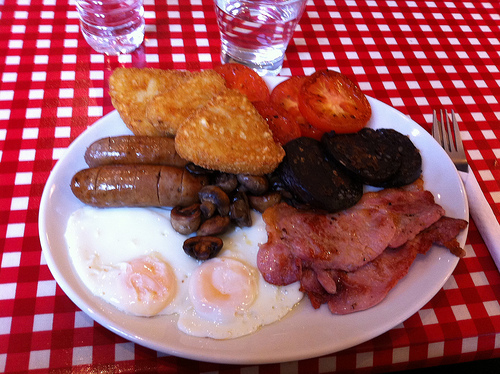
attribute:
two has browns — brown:
[108, 61, 287, 177]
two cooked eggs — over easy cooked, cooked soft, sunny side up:
[66, 198, 304, 342]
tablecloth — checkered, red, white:
[1, 1, 499, 373]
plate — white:
[38, 74, 470, 365]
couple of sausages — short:
[73, 134, 201, 208]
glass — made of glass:
[213, 2, 307, 78]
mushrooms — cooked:
[171, 159, 280, 260]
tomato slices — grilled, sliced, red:
[214, 59, 372, 142]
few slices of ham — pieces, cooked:
[259, 176, 468, 319]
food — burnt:
[269, 128, 425, 210]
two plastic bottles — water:
[75, 1, 308, 77]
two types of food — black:
[168, 127, 425, 263]